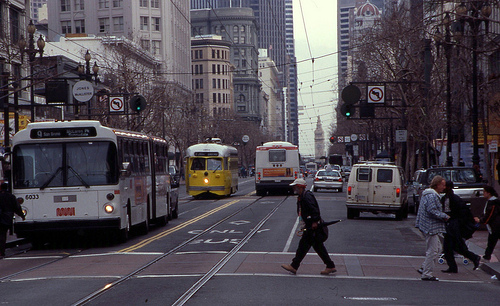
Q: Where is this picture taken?
A: A city.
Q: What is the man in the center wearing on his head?
A: A baseball cap.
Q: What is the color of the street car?
A: Yellow.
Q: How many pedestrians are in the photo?
A: Five.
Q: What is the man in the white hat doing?
A: Crossing the street.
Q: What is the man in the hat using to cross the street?
A: The crosswalk.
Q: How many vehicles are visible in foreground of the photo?
A: Six.